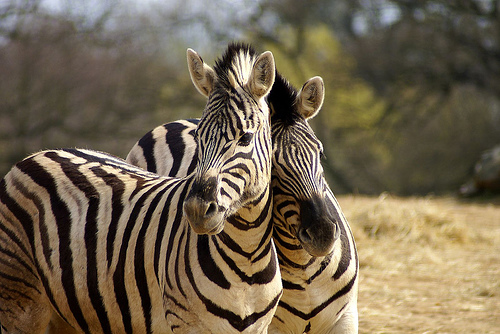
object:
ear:
[186, 48, 216, 99]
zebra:
[2, 41, 285, 333]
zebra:
[124, 76, 360, 334]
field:
[333, 195, 499, 334]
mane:
[212, 37, 259, 97]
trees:
[1, 0, 500, 200]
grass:
[342, 188, 500, 334]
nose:
[182, 196, 218, 219]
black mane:
[270, 67, 299, 126]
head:
[185, 46, 277, 237]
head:
[266, 74, 340, 256]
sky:
[0, 1, 500, 67]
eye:
[237, 132, 254, 147]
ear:
[246, 50, 277, 99]